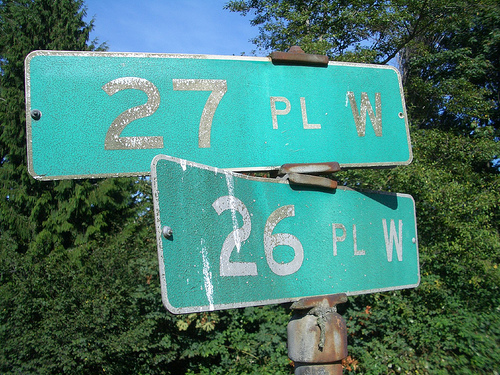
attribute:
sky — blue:
[118, 8, 216, 56]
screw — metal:
[162, 226, 174, 242]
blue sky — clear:
[77, 2, 409, 78]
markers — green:
[15, 43, 432, 320]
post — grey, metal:
[278, 299, 349, 372]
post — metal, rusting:
[287, 290, 348, 373]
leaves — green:
[414, 15, 496, 123]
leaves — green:
[423, 128, 495, 284]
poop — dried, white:
[173, 250, 261, 305]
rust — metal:
[286, 294, 351, 374]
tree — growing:
[4, 1, 151, 374]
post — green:
[25, 51, 412, 166]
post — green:
[153, 150, 431, 302]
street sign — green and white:
[27, 44, 412, 184]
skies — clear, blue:
[1, 1, 498, 169]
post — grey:
[276, 292, 356, 372]